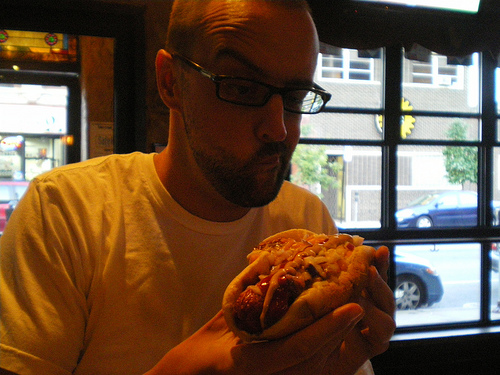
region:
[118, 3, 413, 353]
a man eating a hotdog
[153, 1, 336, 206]
a man making a funny face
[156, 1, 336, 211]
a man wearing glasses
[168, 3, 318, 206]
a man with a beard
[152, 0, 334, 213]
a man with a close shaven head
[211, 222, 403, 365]
two hands holding a hotdog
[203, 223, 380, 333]
a hot-dog with mustard and katchup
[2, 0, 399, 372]
a man wearing a white t-shirt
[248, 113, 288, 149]
the nose of a man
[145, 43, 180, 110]
the ear of a man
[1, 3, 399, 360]
a man eating a hotdog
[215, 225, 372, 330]
a hotdog with mustard and katchup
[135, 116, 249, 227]
the neck of a man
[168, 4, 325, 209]
middle aged man with glasses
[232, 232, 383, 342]
loaded chili dog with cheese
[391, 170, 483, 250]
window with blue car outside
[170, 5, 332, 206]
man with confused look on face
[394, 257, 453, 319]
view of front wheel of car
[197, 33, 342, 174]
man with one raised eyebrow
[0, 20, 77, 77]
bottom half of stained glass window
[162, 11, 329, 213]
man with beard looking confused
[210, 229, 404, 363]
loaded chili dog on hotdog roll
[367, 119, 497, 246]
view of street outside window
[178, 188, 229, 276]
part of a coolar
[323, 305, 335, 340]
part of a finger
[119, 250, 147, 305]
ppart of a top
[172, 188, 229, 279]
part of a collar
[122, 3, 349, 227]
a man wearing black glasses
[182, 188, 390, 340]
a hotdog in a bun with cheese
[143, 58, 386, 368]
a man holding a hotdog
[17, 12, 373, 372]
a man wearing a tshirt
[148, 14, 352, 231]
a man with facial hair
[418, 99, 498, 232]
a tree outside the building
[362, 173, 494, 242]
a car parked on the side of the road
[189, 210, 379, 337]
a hotdog with ketchup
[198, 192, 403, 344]
a hotdog with cheese